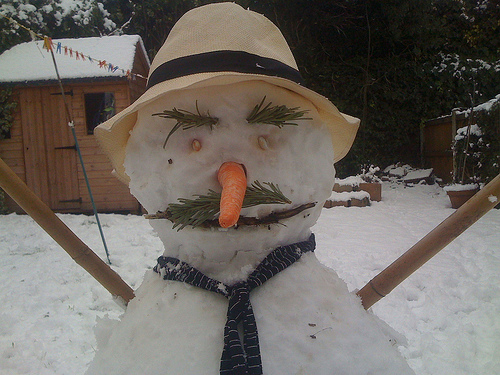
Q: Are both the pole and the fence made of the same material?
A: Yes, both the pole and the fence are made of wood.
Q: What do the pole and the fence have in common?
A: The material, both the pole and the fence are wooden.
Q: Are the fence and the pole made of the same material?
A: Yes, both the fence and the pole are made of wood.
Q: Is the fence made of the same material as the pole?
A: Yes, both the fence and the pole are made of wood.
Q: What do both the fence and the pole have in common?
A: The material, both the fence and the pole are wooden.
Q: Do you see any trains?
A: No, there are no trains.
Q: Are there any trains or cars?
A: No, there are no trains or cars.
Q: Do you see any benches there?
A: No, there are no benches.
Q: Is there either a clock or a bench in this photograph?
A: No, there are no benches or clocks.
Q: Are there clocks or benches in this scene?
A: No, there are no benches or clocks.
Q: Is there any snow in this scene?
A: Yes, there is snow.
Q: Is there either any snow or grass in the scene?
A: Yes, there is snow.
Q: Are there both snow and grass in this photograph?
A: No, there is snow but no grass.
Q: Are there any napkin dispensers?
A: No, there are no napkin dispensers.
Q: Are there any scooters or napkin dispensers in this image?
A: No, there are no napkin dispensers or scooters.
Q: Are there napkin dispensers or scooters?
A: No, there are no napkin dispensers or scooters.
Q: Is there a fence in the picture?
A: Yes, there is a fence.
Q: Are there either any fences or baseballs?
A: Yes, there is a fence.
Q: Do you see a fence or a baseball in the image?
A: Yes, there is a fence.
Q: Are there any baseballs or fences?
A: Yes, there is a fence.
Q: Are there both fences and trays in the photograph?
A: No, there is a fence but no trays.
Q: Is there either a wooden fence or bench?
A: Yes, there is a wood fence.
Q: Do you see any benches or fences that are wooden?
A: Yes, the fence is wooden.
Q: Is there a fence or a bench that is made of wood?
A: Yes, the fence is made of wood.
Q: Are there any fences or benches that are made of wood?
A: Yes, the fence is made of wood.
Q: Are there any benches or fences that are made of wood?
A: Yes, the fence is made of wood.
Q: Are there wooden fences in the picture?
A: Yes, there is a wood fence.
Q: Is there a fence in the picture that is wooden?
A: Yes, there is a fence that is wooden.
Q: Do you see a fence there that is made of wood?
A: Yes, there is a fence that is made of wood.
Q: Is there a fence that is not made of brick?
A: Yes, there is a fence that is made of wood.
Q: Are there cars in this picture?
A: No, there are no cars.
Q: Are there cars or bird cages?
A: No, there are no cars or bird cages.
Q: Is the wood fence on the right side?
A: Yes, the fence is on the right of the image.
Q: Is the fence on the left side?
A: No, the fence is on the right of the image.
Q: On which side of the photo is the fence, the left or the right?
A: The fence is on the right of the image.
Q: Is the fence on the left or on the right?
A: The fence is on the right of the image.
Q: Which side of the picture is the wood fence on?
A: The fence is on the right of the image.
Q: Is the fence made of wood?
A: Yes, the fence is made of wood.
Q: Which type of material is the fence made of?
A: The fence is made of wood.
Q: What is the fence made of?
A: The fence is made of wood.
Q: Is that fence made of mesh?
A: No, the fence is made of wood.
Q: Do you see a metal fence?
A: No, there is a fence but it is made of wood.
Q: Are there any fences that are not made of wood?
A: No, there is a fence but it is made of wood.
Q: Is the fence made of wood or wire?
A: The fence is made of wood.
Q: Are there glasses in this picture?
A: No, there are no glasses.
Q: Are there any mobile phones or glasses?
A: No, there are no glasses or mobile phones.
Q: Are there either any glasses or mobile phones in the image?
A: No, there are no glasses or mobile phones.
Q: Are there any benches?
A: No, there are no benches.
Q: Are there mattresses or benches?
A: No, there are no benches or mattresses.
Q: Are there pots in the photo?
A: Yes, there is a pot.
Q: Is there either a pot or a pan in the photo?
A: Yes, there is a pot.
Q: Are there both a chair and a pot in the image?
A: No, there is a pot but no chairs.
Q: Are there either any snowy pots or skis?
A: Yes, there is a snowy pot.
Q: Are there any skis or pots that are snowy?
A: Yes, the pot is snowy.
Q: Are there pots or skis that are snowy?
A: Yes, the pot is snowy.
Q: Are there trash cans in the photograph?
A: No, there are no trash cans.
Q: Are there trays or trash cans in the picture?
A: No, there are no trash cans or trays.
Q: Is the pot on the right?
A: Yes, the pot is on the right of the image.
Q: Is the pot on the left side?
A: No, the pot is on the right of the image.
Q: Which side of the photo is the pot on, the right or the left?
A: The pot is on the right of the image.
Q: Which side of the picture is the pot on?
A: The pot is on the right of the image.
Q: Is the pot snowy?
A: Yes, the pot is snowy.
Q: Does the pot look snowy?
A: Yes, the pot is snowy.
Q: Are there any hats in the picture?
A: Yes, there is a hat.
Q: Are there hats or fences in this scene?
A: Yes, there is a hat.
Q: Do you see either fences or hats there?
A: Yes, there is a hat.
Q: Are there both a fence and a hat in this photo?
A: Yes, there are both a hat and a fence.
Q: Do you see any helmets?
A: No, there are no helmets.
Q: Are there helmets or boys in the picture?
A: No, there are no helmets or boys.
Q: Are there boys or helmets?
A: No, there are no helmets or boys.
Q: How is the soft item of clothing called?
A: The clothing item is a hat.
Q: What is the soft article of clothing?
A: The clothing item is a hat.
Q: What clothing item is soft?
A: The clothing item is a hat.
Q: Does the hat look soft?
A: Yes, the hat is soft.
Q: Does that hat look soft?
A: Yes, the hat is soft.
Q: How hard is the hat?
A: The hat is soft.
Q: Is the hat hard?
A: No, the hat is soft.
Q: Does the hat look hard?
A: No, the hat is soft.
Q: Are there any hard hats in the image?
A: No, there is a hat but it is soft.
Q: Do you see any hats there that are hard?
A: No, there is a hat but it is soft.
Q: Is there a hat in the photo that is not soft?
A: No, there is a hat but it is soft.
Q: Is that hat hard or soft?
A: The hat is soft.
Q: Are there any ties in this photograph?
A: Yes, there is a tie.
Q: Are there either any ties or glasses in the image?
A: Yes, there is a tie.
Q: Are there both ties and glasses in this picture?
A: No, there is a tie but no glasses.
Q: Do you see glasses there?
A: No, there are no glasses.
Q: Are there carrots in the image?
A: Yes, there is a carrot.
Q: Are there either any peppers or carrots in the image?
A: Yes, there is a carrot.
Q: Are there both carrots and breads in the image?
A: No, there is a carrot but no breads.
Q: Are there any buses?
A: No, there are no buses.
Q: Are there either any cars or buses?
A: No, there are no buses or cars.